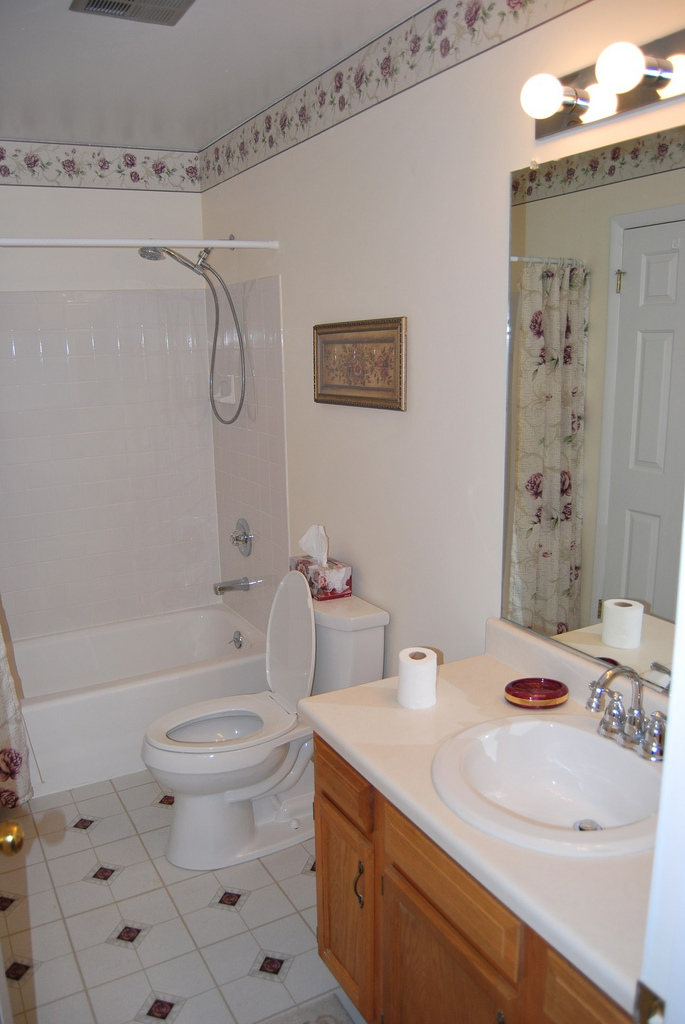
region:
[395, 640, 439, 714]
the toilet paper is white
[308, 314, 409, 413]
the picture frame is on the wall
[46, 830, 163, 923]
the square tile is cream and red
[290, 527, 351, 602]
the tissue box has a floral design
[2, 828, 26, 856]
the door nob is gold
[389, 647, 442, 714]
the toilet paper is on top of the counter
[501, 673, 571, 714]
the soap dish is red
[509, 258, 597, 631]
the shower curtain has floral design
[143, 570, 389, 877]
the toilet is the color white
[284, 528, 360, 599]
Tissue box with red flowers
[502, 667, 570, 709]
Circular red and gold bowl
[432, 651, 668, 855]
White sink with silver faucets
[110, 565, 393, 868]
Toliet seat with the top up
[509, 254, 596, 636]
Flowered white shower curtain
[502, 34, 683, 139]
Two round lights that are on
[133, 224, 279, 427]
Hung up silver shower nozzle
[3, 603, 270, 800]
A white bathtub.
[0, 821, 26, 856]
A round gold knob.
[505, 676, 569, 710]
Red and gold dish on the counter.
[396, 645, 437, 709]
White roll of toilet paper on the counter.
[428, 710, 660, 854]
An oval white sink.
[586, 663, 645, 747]
A silver faucet on the sink.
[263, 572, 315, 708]
A white toilet seat lid.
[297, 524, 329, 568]
A white tissue coming out of a box.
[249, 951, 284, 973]
tile on the floor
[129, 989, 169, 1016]
tile on the floor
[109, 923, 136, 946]
tile on the floor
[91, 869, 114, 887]
tile on the floor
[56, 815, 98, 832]
tile on the floor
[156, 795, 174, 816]
tile on the floor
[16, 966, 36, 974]
tile on the floor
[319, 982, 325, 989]
tile on the floor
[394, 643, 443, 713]
roll of toilet paper on counter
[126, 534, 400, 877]
toilet lid is open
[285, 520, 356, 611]
box of tissue on toilet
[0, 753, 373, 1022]
floor tile is black and white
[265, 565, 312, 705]
an open toilet lid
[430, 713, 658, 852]
a sink in a counter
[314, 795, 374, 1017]
a wooden cabinet door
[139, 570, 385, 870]
a toilet in a bathroom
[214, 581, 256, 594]
a tub faucet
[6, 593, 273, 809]
a bathtub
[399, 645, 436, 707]
a roll of toilet paper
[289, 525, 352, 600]
box if tissueds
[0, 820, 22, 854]
a golden door knob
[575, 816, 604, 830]
a drain in a sink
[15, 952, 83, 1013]
A tile in a floor.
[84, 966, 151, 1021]
A tile in a floor.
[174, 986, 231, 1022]
A tile in a floor.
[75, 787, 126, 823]
A tile in a floor.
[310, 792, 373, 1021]
A door for a cabinet.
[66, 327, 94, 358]
A tile in a wall.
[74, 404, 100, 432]
A tile in a wall.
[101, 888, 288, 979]
tile on the ground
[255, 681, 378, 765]
corner of the counter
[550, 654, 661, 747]
faucet above the sink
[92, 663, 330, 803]
open toilet next to sink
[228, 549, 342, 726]
back of the toilet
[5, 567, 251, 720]
tub next to toilet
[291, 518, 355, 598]
open floral decorated box of tissue